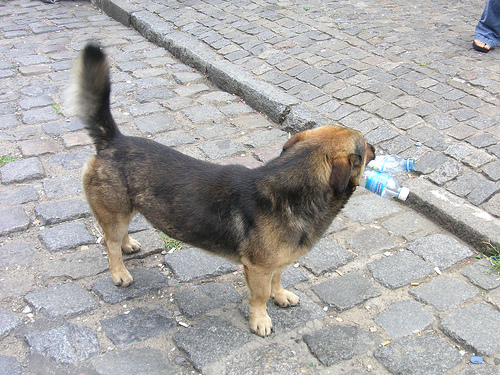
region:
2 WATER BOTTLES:
[356, 145, 421, 220]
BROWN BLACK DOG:
[67, 37, 377, 332]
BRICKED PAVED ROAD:
[361, 258, 477, 361]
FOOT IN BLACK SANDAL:
[470, 32, 489, 53]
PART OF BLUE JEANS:
[466, 2, 498, 49]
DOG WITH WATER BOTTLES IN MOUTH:
[72, 72, 422, 334]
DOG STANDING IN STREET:
[72, 44, 398, 366]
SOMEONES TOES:
[473, 40, 498, 50]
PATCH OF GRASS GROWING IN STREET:
[1, 147, 16, 177]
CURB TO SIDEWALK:
[199, 56, 329, 124]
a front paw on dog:
[243, 305, 278, 339]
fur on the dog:
[160, 169, 214, 211]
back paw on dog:
[112, 264, 138, 294]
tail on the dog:
[75, 45, 122, 137]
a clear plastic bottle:
[372, 171, 396, 198]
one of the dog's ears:
[328, 144, 355, 187]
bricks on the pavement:
[317, 22, 411, 85]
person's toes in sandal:
[470, 35, 487, 52]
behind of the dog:
[80, 151, 130, 189]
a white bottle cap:
[400, 183, 418, 207]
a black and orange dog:
[60, 27, 422, 342]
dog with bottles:
[33, 10, 492, 347]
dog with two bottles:
[30, 20, 489, 318]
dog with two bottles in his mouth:
[29, 15, 459, 369]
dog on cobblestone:
[26, 29, 465, 372]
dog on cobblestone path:
[11, 15, 492, 346]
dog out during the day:
[19, 13, 494, 357]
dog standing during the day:
[35, 16, 442, 369]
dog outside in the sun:
[11, 18, 497, 300]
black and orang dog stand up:
[41, 7, 444, 365]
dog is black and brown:
[53, 80, 342, 366]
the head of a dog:
[278, 117, 383, 210]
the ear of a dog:
[322, 150, 363, 203]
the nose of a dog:
[368, 144, 380, 161]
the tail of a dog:
[58, 35, 128, 142]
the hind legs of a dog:
[96, 215, 140, 290]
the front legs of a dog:
[236, 252, 303, 345]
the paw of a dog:
[248, 307, 276, 339]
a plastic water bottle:
[353, 162, 416, 206]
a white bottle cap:
[396, 182, 411, 204]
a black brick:
[308, 265, 383, 314]